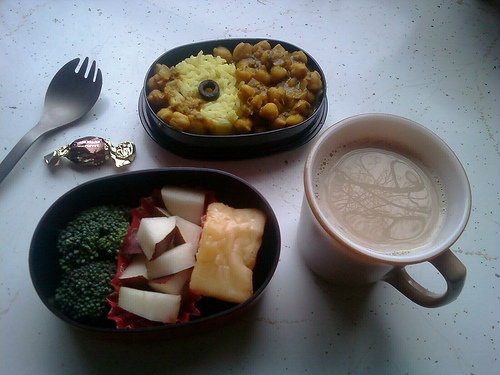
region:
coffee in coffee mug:
[302, 109, 474, 321]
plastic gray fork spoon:
[2, 54, 100, 189]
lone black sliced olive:
[200, 83, 217, 98]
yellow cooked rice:
[176, 54, 238, 125]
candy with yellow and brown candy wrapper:
[45, 132, 132, 162]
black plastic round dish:
[30, 163, 280, 333]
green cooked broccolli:
[55, 200, 126, 261]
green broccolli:
[55, 256, 117, 313]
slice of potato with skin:
[116, 283, 179, 319]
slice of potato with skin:
[135, 214, 177, 257]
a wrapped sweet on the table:
[38, 136, 149, 166]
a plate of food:
[21, 163, 288, 330]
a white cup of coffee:
[301, 111, 470, 310]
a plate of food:
[138, 36, 330, 162]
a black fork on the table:
[0, 55, 106, 180]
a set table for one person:
[0, 0, 496, 372]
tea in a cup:
[298, 107, 475, 313]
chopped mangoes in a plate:
[106, 179, 212, 331]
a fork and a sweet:
[0, 57, 142, 185]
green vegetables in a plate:
[55, 202, 132, 326]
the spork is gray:
[0, 41, 94, 197]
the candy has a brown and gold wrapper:
[27, 130, 144, 167]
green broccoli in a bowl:
[13, 170, 298, 347]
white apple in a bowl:
[116, 170, 198, 338]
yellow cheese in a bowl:
[190, 197, 265, 310]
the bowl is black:
[20, 164, 302, 346]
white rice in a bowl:
[172, 48, 240, 131]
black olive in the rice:
[191, 77, 223, 98]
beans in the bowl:
[223, 37, 333, 138]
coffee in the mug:
[312, 103, 472, 309]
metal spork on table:
[0, 49, 124, 158]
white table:
[40, 13, 431, 42]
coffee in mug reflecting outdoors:
[279, 116, 495, 312]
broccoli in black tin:
[38, 181, 119, 295]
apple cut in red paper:
[111, 171, 192, 334]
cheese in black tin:
[196, 182, 272, 327]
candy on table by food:
[31, 132, 140, 172]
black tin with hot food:
[128, 28, 330, 156]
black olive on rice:
[188, 73, 220, 93]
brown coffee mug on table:
[287, 153, 447, 308]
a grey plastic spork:
[1, 52, 113, 201]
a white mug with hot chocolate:
[290, 110, 482, 320]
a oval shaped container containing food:
[134, 35, 329, 154]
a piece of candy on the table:
[32, 120, 144, 177]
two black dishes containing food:
[21, 23, 336, 350]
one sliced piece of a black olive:
[190, 70, 230, 106]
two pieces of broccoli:
[47, 169, 129, 334]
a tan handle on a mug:
[388, 237, 476, 320]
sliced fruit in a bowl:
[112, 180, 217, 340]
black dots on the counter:
[22, 5, 489, 355]